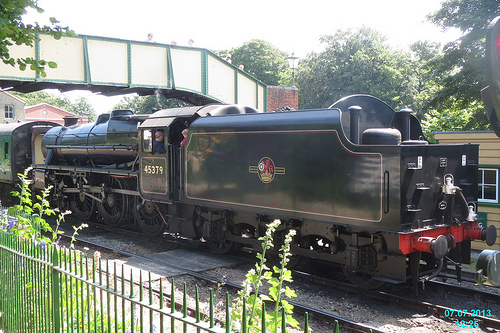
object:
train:
[0, 93, 499, 291]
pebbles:
[321, 294, 363, 316]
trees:
[299, 39, 446, 123]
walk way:
[95, 243, 249, 284]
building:
[433, 130, 500, 253]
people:
[144, 33, 157, 43]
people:
[170, 38, 177, 45]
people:
[186, 38, 195, 47]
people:
[221, 54, 233, 64]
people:
[236, 64, 246, 72]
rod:
[76, 252, 86, 332]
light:
[482, 14, 499, 139]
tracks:
[85, 229, 492, 329]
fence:
[0, 230, 345, 332]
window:
[477, 164, 497, 204]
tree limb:
[4, 13, 79, 44]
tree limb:
[0, 45, 57, 82]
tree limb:
[411, 52, 468, 79]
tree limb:
[458, 106, 490, 134]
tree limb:
[422, 5, 487, 32]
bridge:
[0, 25, 267, 114]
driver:
[153, 131, 167, 154]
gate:
[0, 231, 343, 332]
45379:
[144, 165, 164, 175]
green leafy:
[10, 165, 54, 239]